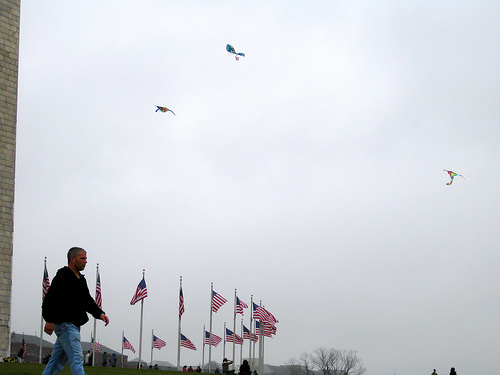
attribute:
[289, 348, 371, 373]
tree — without leaves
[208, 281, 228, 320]
flags — flying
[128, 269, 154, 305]
flags — flying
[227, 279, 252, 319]
flags — flying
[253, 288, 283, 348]
flags — flying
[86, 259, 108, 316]
flags — flying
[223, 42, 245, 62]
kite — blue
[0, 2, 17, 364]
building — tan, brick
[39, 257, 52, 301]
flag — american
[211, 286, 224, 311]
flag — american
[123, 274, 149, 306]
flag — american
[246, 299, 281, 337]
flag — american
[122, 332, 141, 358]
flag — american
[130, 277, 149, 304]
flag — red, white, Blue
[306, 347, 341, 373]
tree — bare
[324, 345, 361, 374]
tree — bare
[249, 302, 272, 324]
flag — American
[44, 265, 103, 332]
shirt — black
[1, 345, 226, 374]
grass — green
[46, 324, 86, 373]
jeans — blue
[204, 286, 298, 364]
flag — american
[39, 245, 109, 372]
man — walking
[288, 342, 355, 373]
tree — leafless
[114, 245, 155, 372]
flag — american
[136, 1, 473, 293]
sky — overcast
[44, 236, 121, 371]
jacket — black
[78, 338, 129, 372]
building — in background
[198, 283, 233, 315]
flag — American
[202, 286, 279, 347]
flags — blowing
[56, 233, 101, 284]
hair — short, gray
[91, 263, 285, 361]
flags — in motion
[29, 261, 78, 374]
flag — American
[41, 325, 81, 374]
pants — man's blue jean 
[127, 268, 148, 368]
flag — american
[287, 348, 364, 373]
tree — without leaves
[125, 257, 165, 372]
pole — long, gray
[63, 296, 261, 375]
flag — American